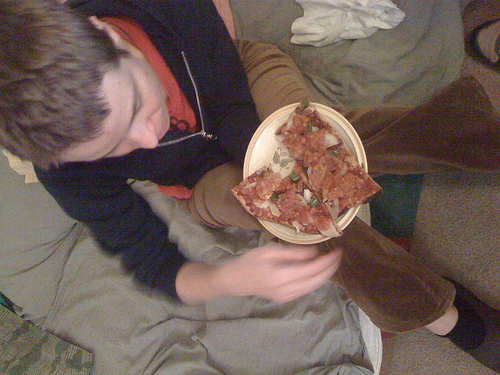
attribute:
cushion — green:
[4, 304, 81, 374]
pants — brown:
[195, 33, 481, 356]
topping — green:
[288, 173, 300, 178]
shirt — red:
[177, 101, 192, 130]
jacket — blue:
[1, 13, 348, 310]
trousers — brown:
[192, 37, 496, 347]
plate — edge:
[238, 100, 371, 245]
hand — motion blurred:
[215, 244, 347, 303]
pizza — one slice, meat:
[230, 155, 341, 241]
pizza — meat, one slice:
[276, 98, 384, 220]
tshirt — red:
[100, 15, 199, 134]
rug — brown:
[382, 14, 496, 374]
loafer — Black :
[440, 277, 499, 373]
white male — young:
[0, 1, 498, 333]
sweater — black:
[34, 29, 267, 313]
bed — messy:
[0, 0, 483, 372]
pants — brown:
[331, 69, 498, 358]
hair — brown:
[2, 2, 122, 162]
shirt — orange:
[91, 14, 199, 152]